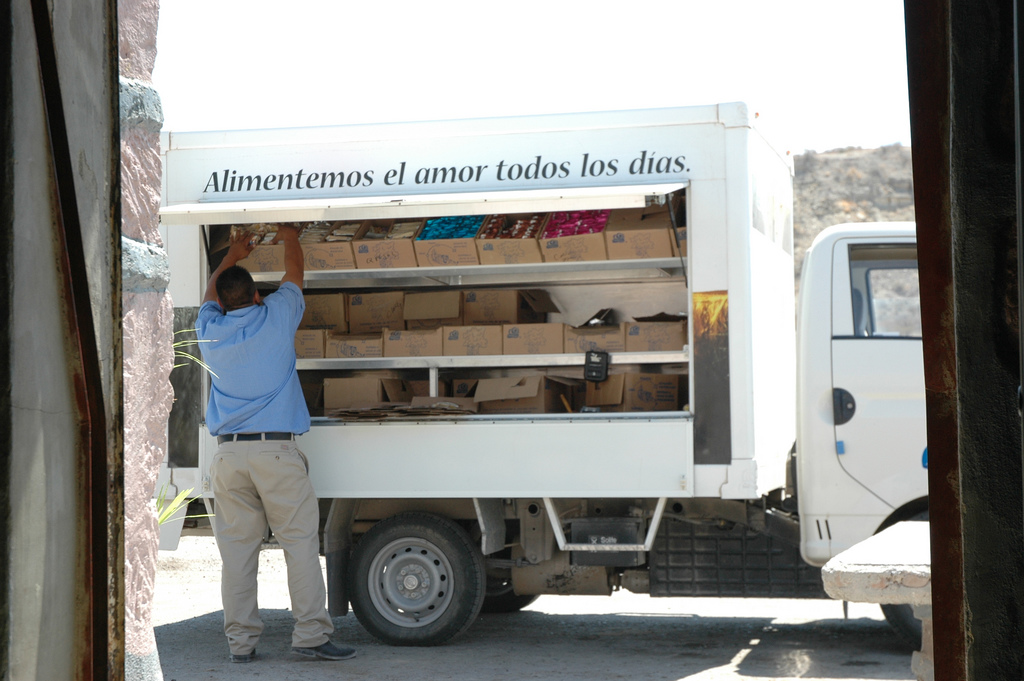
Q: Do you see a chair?
A: No, there are no chairs.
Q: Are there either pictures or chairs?
A: No, there are no chairs or pictures.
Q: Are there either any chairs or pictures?
A: No, there are no chairs or pictures.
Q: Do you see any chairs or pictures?
A: No, there are no chairs or pictures.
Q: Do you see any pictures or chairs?
A: No, there are no chairs or pictures.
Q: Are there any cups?
A: No, there are no cups.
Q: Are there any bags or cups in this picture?
A: No, there are no cups or bags.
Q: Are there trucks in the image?
A: Yes, there is a truck.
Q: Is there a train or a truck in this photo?
A: Yes, there is a truck.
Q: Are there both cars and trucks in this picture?
A: No, there is a truck but no cars.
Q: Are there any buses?
A: No, there are no buses.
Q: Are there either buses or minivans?
A: No, there are no buses or minivans.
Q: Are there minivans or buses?
A: No, there are no buses or minivans.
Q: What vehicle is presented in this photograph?
A: The vehicle is a truck.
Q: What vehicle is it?
A: The vehicle is a truck.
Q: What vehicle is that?
A: This is a truck.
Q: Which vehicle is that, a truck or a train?
A: This is a truck.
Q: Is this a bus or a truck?
A: This is a truck.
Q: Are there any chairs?
A: No, there are no chairs.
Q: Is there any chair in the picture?
A: No, there are no chairs.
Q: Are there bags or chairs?
A: No, there are no chairs or bags.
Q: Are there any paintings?
A: No, there are no paintings.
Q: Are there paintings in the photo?
A: No, there are no paintings.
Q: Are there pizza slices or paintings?
A: No, there are no paintings or pizza slices.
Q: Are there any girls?
A: No, there are no girls.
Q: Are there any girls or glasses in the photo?
A: No, there are no girls or glasses.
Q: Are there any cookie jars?
A: No, there are no cookie jars.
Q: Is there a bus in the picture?
A: No, there are no buses.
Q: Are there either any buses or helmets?
A: No, there are no buses or helmets.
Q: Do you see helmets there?
A: No, there are no helmets.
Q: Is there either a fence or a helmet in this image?
A: No, there are no helmets or fences.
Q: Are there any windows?
A: Yes, there is a window.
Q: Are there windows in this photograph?
A: Yes, there is a window.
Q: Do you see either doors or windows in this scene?
A: Yes, there is a window.